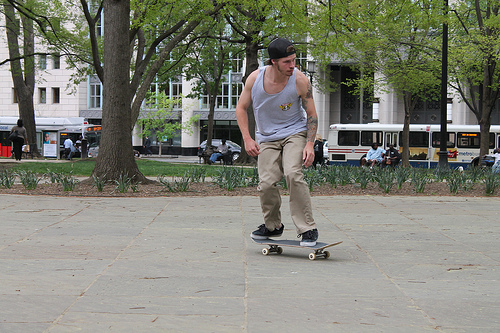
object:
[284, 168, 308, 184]
knees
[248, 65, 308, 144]
man's shirt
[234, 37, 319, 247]
man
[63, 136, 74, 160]
man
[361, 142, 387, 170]
man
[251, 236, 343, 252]
board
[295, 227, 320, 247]
shoe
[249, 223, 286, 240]
shoe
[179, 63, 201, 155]
column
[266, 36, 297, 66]
cap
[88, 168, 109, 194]
plant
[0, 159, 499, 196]
garden area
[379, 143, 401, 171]
man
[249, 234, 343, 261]
skateboard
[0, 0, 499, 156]
building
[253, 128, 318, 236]
pants